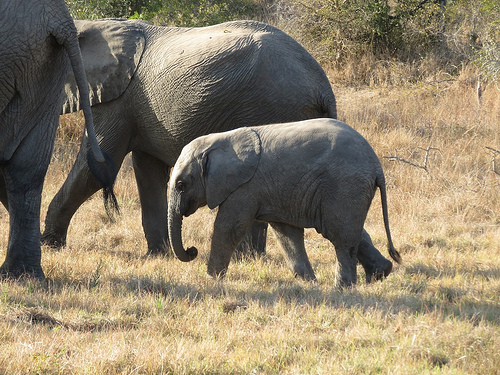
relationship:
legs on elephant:
[327, 210, 391, 287] [164, 115, 405, 290]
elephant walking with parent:
[164, 115, 405, 290] [1, 0, 122, 283]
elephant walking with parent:
[164, 115, 405, 290] [41, 16, 339, 259]